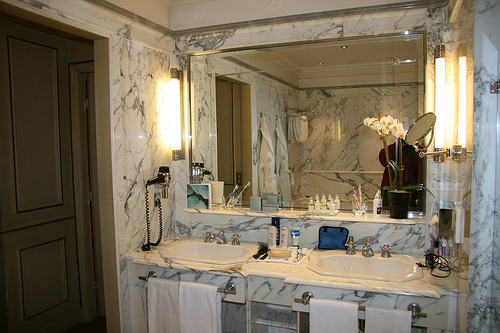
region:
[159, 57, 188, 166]
a mounted light on a wall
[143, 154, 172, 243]
a hair dryer mounted to a wall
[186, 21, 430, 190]
large mirror on the wall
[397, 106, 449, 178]
a small mirror mounted to a wall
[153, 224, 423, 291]
two bathroom sinks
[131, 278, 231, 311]
two towels hanging on a towel rod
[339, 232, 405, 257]
a bathroom sink faucet and handles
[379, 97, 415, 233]
a tall flower in a pot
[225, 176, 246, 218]
a blue toothbrush in a glass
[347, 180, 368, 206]
a red toothbrush in a glass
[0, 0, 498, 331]
A bathroom scene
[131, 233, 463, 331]
This is a bathroom counter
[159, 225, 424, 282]
Two sinks are on the counter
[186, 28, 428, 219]
A mirror is on the wall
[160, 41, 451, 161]
Lights are on both sides of the mirror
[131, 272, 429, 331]
Towels are hanging from the counter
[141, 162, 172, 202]
A hairdryer is on the wall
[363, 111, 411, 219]
Flowers are in front of the mirror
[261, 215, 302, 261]
Toiletries are on the counter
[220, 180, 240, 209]
A toothbrush is in a glass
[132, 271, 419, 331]
the towels are white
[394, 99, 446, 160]
mirror on the wall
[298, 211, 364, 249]
blue bag on counter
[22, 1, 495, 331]
wall and sink made of marble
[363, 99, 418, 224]
flowers in a pot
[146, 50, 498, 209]
bathroom lights are turned on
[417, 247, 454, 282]
black cord on counter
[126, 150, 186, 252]
hair dryer on wall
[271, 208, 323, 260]
containers on the counter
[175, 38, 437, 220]
mirror above the sinks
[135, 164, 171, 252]
A silver and black blowdryer.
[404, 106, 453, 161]
A round moveable mirror attached to the wall.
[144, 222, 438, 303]
A double sink.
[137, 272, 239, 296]
A silver towel rack.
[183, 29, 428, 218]
A large silver framed bathroom mirror.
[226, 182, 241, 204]
A blue and white toothbrush.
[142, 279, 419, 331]
Hanging white towels.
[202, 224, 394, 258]
Silver sink fixtures.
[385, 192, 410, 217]
A black flowerpot.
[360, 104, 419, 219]
A white flower plant.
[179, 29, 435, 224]
a large bathroom mirror.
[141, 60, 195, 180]
a light on a mirror.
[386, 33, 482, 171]
a light near a mirror.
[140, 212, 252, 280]
a bathroom sink under a mirror.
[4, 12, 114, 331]
a doorway in a bathroom.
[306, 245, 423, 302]
a right sink in a bathroom.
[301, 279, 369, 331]
a towel on a towel rack.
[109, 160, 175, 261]
a device on a wall.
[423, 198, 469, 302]
items near a mirror.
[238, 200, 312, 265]
clutter on a bathroom sink.